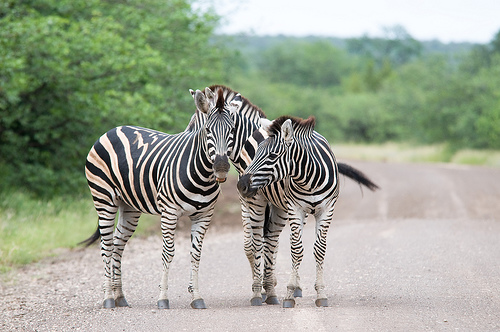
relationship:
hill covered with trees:
[9, 0, 497, 224] [1, 0, 255, 203]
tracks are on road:
[356, 160, 468, 220] [2, 135, 495, 331]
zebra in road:
[76, 89, 241, 310] [2, 135, 495, 331]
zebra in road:
[187, 84, 376, 303] [2, 135, 495, 331]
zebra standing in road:
[236, 115, 339, 307] [2, 135, 495, 331]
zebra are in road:
[76, 89, 236, 310] [2, 135, 495, 331]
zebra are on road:
[76, 89, 236, 310] [2, 135, 495, 331]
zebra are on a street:
[76, 89, 236, 310] [2, 135, 495, 331]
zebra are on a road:
[76, 89, 236, 310] [2, 135, 495, 331]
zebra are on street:
[76, 89, 236, 310] [2, 135, 495, 331]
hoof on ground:
[192, 296, 207, 310] [23, 245, 472, 330]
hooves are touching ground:
[100, 284, 335, 311] [23, 245, 472, 330]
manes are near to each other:
[197, 85, 315, 138] [183, 83, 274, 175]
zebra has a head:
[76, 89, 241, 310] [193, 88, 242, 183]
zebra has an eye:
[76, 89, 241, 310] [206, 126, 213, 135]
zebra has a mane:
[76, 89, 241, 310] [213, 87, 228, 112]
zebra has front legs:
[76, 89, 241, 310] [157, 200, 215, 294]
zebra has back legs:
[76, 89, 241, 310] [92, 203, 139, 298]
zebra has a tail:
[76, 89, 241, 310] [76, 219, 103, 254]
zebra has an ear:
[76, 89, 241, 310] [194, 91, 214, 117]